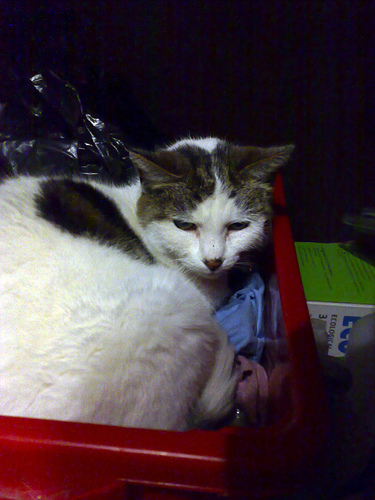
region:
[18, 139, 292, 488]
This is a cat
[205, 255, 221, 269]
The nose of the cat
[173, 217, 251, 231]
The eyes of the cat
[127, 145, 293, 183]
The ears of the cat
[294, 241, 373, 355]
A box near the cat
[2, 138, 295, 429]
A cat in a red box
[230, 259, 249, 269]
The whiskers of the cat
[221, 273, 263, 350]
Blue cloth beneath the cat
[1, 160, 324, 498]
A red box beneath the cat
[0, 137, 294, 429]
The cat has white and black fur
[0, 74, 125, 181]
A black bag behind the cat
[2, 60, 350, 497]
cat laying in red wagon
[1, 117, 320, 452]
white and brown spotted cat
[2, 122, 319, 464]
white and brown cat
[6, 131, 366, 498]
red wagon under cat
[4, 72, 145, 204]
black plastic bag behind cat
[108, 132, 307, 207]
brown ears of cat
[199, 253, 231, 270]
brown nose of cat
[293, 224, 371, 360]
box next to red wagon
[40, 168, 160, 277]
brown spot on cat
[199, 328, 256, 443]
cat's white tail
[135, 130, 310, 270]
the head of a cat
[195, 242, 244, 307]
the nose of a cat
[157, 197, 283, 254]
the eyes on a cat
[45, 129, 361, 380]
a big white cat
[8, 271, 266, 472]
the back end of a cat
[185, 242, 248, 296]
the mouth of a cat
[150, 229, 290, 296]
the whiskers on a cat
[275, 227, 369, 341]
a box near a cat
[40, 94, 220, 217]
a black bag near a back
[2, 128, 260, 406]
the body of a cat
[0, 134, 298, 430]
Cat in red crate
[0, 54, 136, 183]
Black bag behind cat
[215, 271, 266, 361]
Blue bag under cat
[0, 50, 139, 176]
Black bag in red crate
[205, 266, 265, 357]
Blue bag in red crate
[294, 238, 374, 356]
Green and white box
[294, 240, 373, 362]
Green and white box next to red crate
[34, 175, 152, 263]
Black spot on cat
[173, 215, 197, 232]
Eye of cat is opened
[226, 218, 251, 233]
Eye of cat is opened